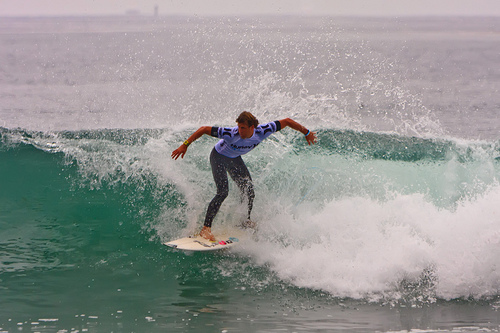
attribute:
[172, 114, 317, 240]
person — surfer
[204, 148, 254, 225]
pants — black, polypropelene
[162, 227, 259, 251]
surfboard — yellow, white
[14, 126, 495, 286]
wave — white, frothy, greenish, breaking, foamy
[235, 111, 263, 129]
hair — brown, short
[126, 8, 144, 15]
ship — offshore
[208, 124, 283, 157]
shirt — polypropelene, purple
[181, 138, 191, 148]
wristband — yellow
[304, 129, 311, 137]
bracelet — blue